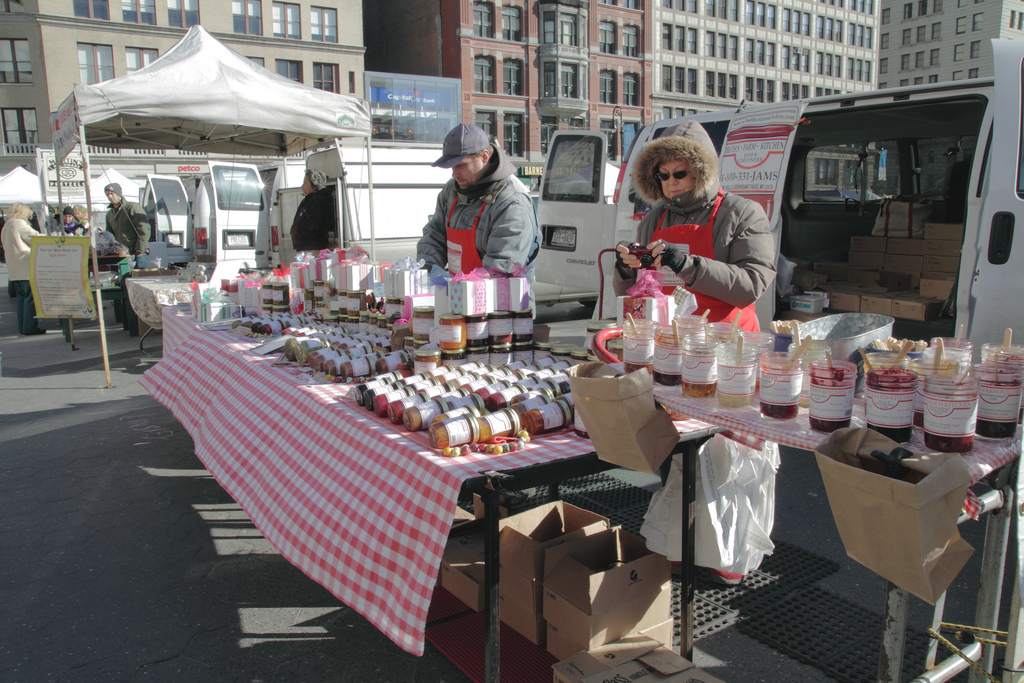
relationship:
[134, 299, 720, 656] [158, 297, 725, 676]
tablecloth covering table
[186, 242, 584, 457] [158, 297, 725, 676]
food sitting on top of table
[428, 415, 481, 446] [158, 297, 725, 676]
jar sitting on top of table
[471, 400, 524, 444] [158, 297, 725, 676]
jar sitting on top of table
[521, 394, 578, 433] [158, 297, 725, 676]
jar sitting on top of table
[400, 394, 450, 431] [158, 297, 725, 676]
jar sitting on top of table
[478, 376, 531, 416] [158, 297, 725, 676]
jar sitting on top of table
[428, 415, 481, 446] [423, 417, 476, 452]
jar containing jam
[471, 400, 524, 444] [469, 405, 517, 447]
jar containing jam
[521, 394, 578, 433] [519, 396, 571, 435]
jar containing jam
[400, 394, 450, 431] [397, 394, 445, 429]
jar containing jam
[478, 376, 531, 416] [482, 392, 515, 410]
jar containing jam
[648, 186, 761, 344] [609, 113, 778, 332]
apron worn over coat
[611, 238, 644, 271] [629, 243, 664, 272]
hand holding cell phone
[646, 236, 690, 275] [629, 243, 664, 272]
hand holding cell phone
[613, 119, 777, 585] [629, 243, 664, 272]
person holding cell phone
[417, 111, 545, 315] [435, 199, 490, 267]
man wearing apron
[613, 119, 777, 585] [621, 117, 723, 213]
person wearing a hood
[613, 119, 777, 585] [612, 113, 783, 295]
person wearing a jacket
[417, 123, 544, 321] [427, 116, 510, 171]
man with cap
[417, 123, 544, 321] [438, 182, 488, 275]
man wearing apron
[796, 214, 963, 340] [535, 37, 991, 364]
boxes in van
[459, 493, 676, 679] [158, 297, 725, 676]
boxes under table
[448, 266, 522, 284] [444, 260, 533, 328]
ribbons on boxes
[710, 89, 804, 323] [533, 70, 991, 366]
door on van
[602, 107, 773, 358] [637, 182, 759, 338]
person in apron